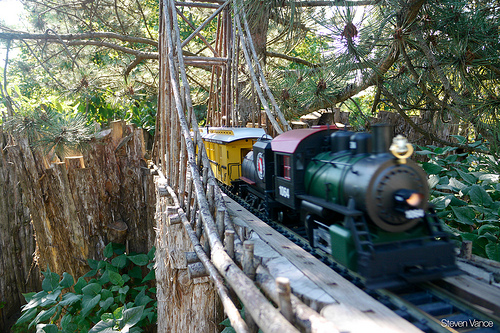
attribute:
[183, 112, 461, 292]
train — black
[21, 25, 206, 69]
branch — brown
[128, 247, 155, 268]
leaf — green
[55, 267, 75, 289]
leaf — green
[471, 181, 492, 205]
leaf — green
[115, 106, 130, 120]
leaf — green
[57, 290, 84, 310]
leaf — green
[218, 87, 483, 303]
train — miniature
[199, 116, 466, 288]
train — black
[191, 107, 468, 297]
train — black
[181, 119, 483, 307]
train — OLD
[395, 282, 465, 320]
tracks — OLD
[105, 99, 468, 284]
train — black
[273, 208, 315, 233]
train wheels — STEEL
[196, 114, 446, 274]
train — black